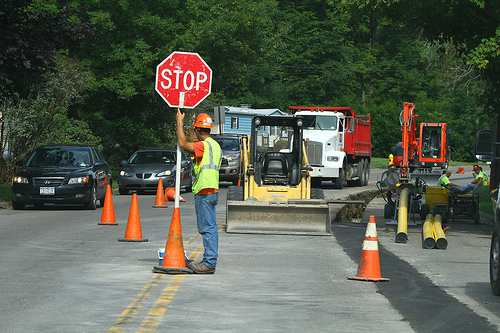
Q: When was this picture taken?
A: Daytime.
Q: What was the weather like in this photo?
A: Sunny.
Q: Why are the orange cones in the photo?
A: To block off part of the street.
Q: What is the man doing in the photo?
A: Holding up a stop sign.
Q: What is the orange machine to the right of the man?
A: A bulldozer.